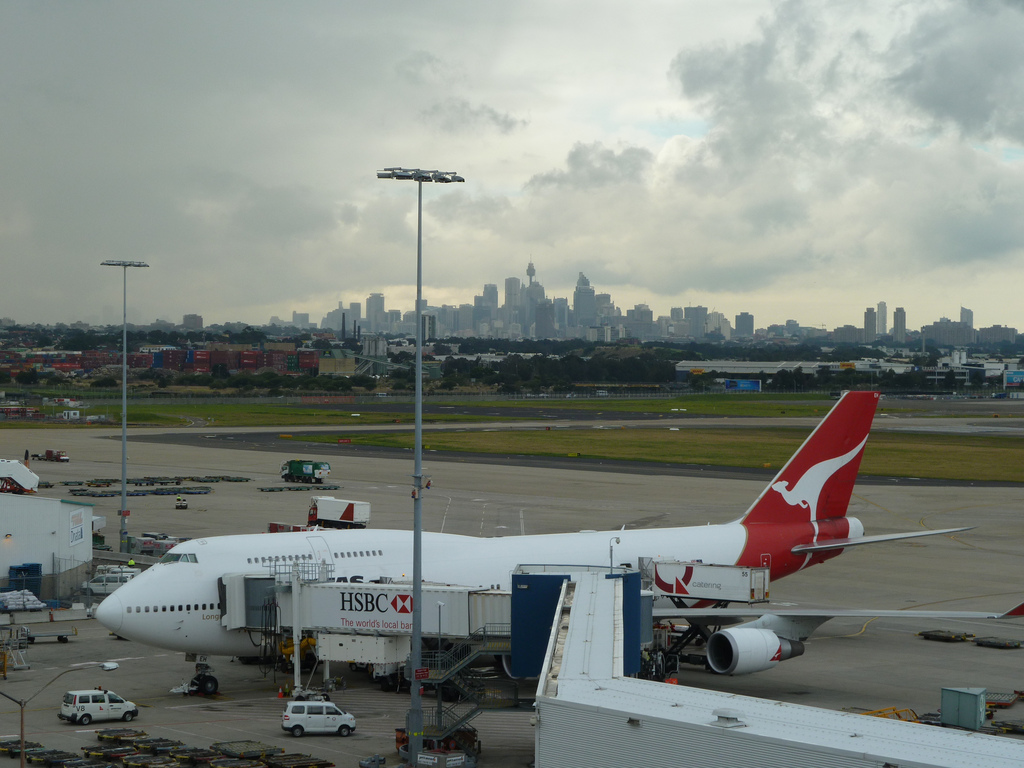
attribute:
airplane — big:
[51, 385, 1000, 709]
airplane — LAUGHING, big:
[62, 379, 973, 687]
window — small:
[127, 600, 143, 617]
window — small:
[125, 608, 139, 627]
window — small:
[153, 605, 157, 621]